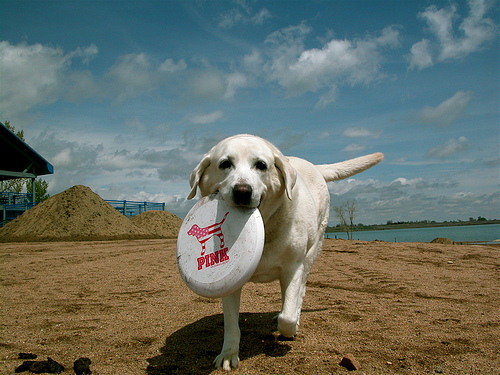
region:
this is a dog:
[178, 132, 383, 369]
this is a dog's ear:
[273, 151, 299, 199]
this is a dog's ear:
[186, 154, 214, 199]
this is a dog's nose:
[233, 183, 253, 200]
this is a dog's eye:
[214, 155, 232, 174]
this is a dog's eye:
[251, 157, 268, 170]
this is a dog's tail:
[312, 151, 382, 186]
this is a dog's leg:
[277, 257, 307, 342]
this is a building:
[2, 125, 164, 236]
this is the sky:
[354, 51, 499, 226]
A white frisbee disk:
[170, 197, 259, 309]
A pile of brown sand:
[4, 172, 165, 251]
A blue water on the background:
[364, 226, 497, 240]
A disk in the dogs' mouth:
[158, 175, 284, 304]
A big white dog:
[206, 128, 396, 240]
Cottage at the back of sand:
[1, 118, 93, 208]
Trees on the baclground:
[358, 214, 495, 227]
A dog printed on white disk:
[165, 210, 237, 256]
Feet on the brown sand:
[188, 336, 273, 373]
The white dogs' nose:
[223, 180, 261, 210]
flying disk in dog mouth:
[155, 175, 272, 307]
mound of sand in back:
[0, 174, 143, 271]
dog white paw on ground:
[205, 328, 254, 373]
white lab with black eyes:
[191, 123, 308, 234]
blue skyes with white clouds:
[168, 30, 370, 117]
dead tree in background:
[337, 201, 360, 248]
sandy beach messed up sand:
[351, 254, 486, 355]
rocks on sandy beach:
[15, 341, 60, 371]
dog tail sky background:
[312, 148, 402, 193]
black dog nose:
[230, 175, 252, 207]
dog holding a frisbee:
[162, 125, 410, 370]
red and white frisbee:
[153, 185, 280, 300]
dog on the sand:
[153, 128, 437, 373]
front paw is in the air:
[268, 308, 306, 343]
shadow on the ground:
[131, 295, 360, 373]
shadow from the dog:
[128, 300, 346, 373]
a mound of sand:
[0, 170, 140, 242]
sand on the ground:
[2, 183, 498, 373]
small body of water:
[308, 207, 497, 250]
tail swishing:
[303, 150, 395, 185]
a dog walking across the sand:
[63, 87, 399, 372]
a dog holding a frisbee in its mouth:
[142, 118, 301, 313]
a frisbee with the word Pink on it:
[166, 196, 262, 293]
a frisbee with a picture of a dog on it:
[163, 189, 263, 294]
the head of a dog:
[166, 121, 301, 219]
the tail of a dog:
[300, 123, 391, 203]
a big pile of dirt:
[3, 183, 150, 258]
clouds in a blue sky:
[23, 0, 487, 122]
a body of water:
[348, 215, 498, 243]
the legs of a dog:
[269, 264, 323, 348]